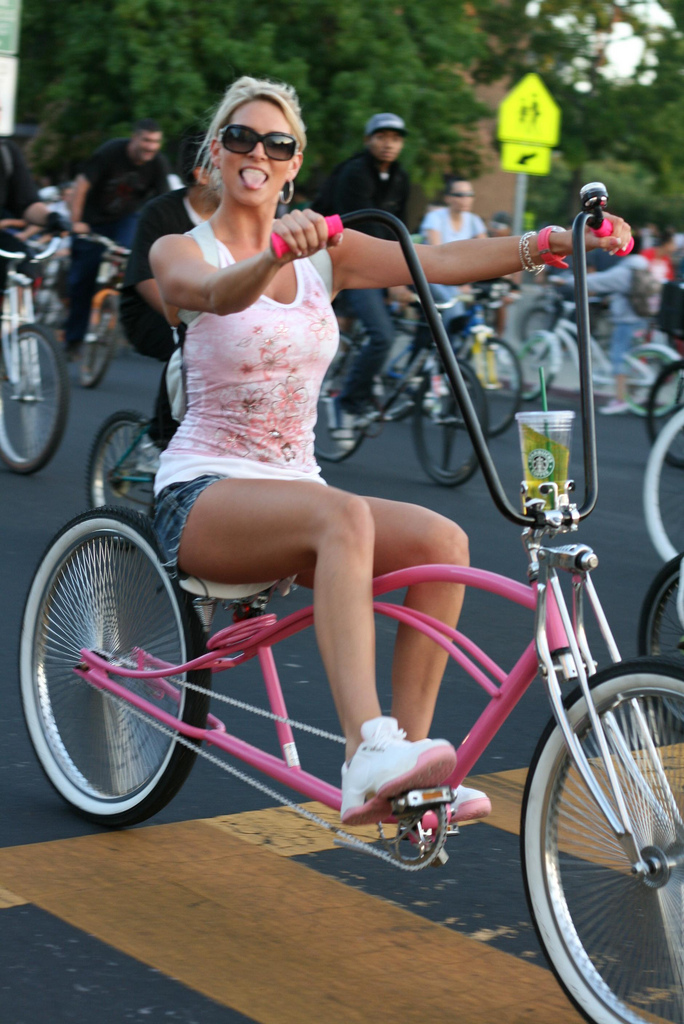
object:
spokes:
[539, 687, 682, 1008]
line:
[0, 747, 680, 1021]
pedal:
[390, 785, 458, 812]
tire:
[17, 506, 212, 829]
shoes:
[340, 715, 456, 825]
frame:
[69, 564, 568, 840]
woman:
[149, 76, 634, 820]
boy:
[316, 112, 416, 452]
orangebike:
[81, 232, 122, 385]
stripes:
[9, 796, 558, 1023]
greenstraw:
[539, 365, 555, 507]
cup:
[515, 367, 575, 510]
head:
[207, 76, 304, 208]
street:
[4, 325, 674, 1024]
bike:
[0, 176, 679, 1019]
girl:
[149, 72, 632, 838]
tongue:
[242, 167, 267, 192]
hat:
[366, 112, 411, 140]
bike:
[44, 230, 121, 392]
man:
[53, 124, 181, 348]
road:
[0, 326, 681, 1019]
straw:
[537, 367, 553, 471]